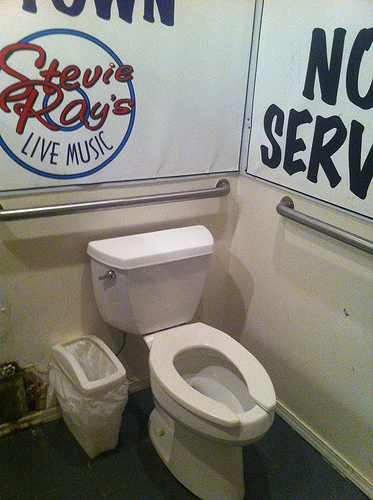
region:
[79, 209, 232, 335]
a white toilet tank.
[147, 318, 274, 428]
a white toilet seat.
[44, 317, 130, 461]
a trash can near a toilet.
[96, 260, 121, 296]
a metal flushing lever.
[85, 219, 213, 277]
a white toilet tank lid.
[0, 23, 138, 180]
a sign behind a toilet.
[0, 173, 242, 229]
A metal bar on a wall.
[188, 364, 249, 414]
a bowl filled with water.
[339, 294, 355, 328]
a dark wall stain.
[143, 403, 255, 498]
the base of a toilet.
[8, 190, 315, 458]
a bathroom area in a building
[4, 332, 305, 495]
this bathroom looks old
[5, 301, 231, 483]
this bathroom looks dirty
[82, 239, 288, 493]
this bathroom is nasty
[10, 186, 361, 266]
towel racks in the bathroom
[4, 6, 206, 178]
some kind of advertisement on the wall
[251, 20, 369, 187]
a sign for customers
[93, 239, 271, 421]
the toilet is white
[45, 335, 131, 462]
the trash basket is white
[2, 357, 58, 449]
a hole in the wall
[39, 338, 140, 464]
A white garbage can next to the toilet.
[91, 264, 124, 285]
The handle on the toilet bowl.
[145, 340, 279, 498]
The toilet is in the bathroom.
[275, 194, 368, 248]
A railing on the wall.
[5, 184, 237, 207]
Railing behind the toilet.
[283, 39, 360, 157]
A sign with black letters on the wall.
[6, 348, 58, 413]
Part of the wall is ripped.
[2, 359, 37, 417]
Pipes in the wall.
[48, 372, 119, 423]
Plastic bag in the garbage can.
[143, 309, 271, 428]
The toilet does not have a lid.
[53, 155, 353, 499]
a publice bathroom toilet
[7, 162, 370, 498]
a public bathroom with toilet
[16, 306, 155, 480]
a white trash can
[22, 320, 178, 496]
a white garbage can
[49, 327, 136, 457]
a small garbage can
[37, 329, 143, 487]
a small trash can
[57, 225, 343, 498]
a white bathroom toilet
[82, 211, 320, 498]
a toilet that is white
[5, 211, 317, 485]
a trash can next to toilet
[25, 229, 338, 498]
a toilet next to garbage can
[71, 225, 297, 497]
Toilet in a bathroom.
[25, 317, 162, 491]
Trash can on the floor.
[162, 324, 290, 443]
Water in the toilet.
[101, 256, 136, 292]
Handle on the tank.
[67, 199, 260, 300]
Tank on the toilet.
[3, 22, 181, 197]
Logo on the wall.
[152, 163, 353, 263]
Handle on the wall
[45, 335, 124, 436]
Bag in the trash can.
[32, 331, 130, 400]
Lid on the trash can.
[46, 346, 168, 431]
White bag in the trash can.